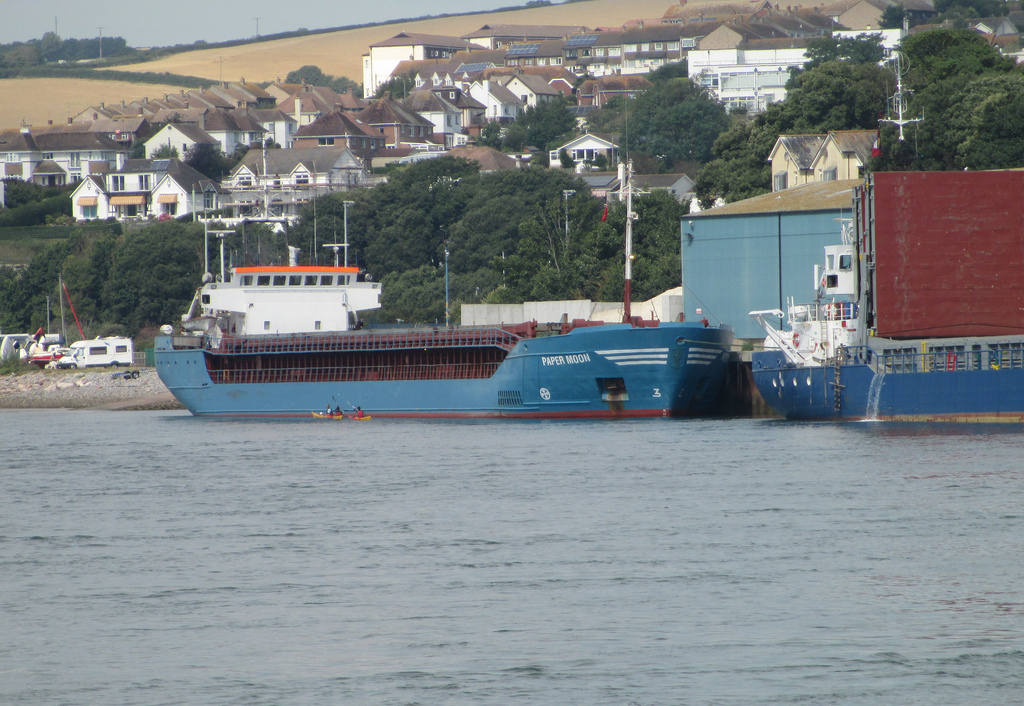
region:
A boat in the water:
[144, 257, 733, 426]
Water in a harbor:
[6, 402, 1021, 698]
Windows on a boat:
[233, 266, 360, 293]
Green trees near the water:
[0, 142, 684, 351]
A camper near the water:
[39, 326, 134, 372]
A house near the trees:
[71, 153, 228, 227]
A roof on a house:
[232, 143, 354, 170]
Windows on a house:
[98, 169, 162, 190]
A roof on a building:
[679, 172, 879, 211]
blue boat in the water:
[147, 298, 736, 432]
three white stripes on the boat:
[596, 330, 674, 381]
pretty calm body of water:
[0, 409, 1023, 703]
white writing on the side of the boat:
[541, 332, 592, 374]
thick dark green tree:
[105, 206, 222, 337]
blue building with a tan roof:
[675, 175, 872, 341]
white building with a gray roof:
[219, 133, 359, 204]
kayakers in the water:
[302, 399, 383, 426]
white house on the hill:
[64, 160, 205, 219]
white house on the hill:
[33, 125, 133, 182]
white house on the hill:
[0, 125, 45, 187]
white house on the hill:
[547, 128, 618, 167]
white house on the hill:
[140, 112, 208, 160]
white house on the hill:
[197, 100, 237, 159]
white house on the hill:
[277, 88, 326, 131]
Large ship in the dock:
[120, 233, 727, 427]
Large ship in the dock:
[726, 151, 1022, 428]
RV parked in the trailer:
[62, 332, 143, 372]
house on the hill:
[543, 123, 624, 182]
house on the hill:
[218, 138, 380, 190]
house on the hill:
[63, 151, 210, 224]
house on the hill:
[410, 81, 477, 158]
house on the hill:
[364, 98, 434, 155]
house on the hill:
[363, 23, 420, 96]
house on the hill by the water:
[62, 166, 208, 223]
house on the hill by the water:
[14, 125, 122, 176]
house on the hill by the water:
[136, 115, 204, 169]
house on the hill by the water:
[181, 99, 242, 154]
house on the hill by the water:
[215, 134, 374, 198]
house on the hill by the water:
[541, 122, 625, 183]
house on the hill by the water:
[760, 128, 869, 183]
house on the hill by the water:
[585, 46, 614, 75]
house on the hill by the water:
[509, 68, 568, 125]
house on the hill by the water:
[469, 64, 521, 131]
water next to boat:
[214, 471, 797, 674]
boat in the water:
[16, 221, 706, 522]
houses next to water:
[2, 25, 731, 308]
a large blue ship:
[147, 308, 735, 419]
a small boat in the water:
[302, 399, 364, 413]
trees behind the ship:
[23, 200, 652, 315]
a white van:
[57, 333, 130, 365]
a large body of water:
[10, 402, 1014, 698]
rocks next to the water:
[7, 361, 159, 400]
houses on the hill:
[7, 23, 992, 192]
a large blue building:
[680, 187, 864, 328]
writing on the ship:
[532, 349, 608, 365]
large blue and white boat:
[169, 297, 701, 457]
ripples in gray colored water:
[38, 432, 105, 487]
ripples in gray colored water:
[172, 628, 224, 677]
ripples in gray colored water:
[532, 595, 575, 638]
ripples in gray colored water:
[779, 596, 841, 647]